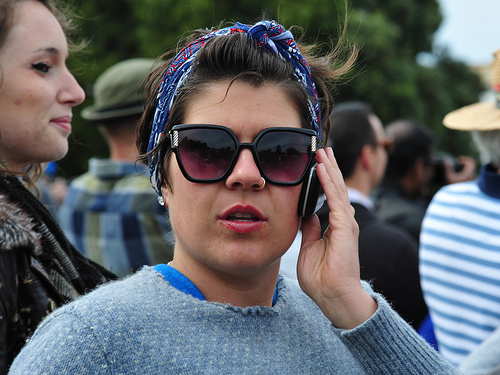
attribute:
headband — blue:
[144, 21, 319, 196]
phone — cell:
[290, 144, 330, 228]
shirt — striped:
[420, 165, 499, 367]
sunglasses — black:
[165, 116, 320, 197]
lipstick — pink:
[214, 199, 275, 243]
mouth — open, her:
[213, 200, 275, 234]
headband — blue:
[137, 17, 333, 181]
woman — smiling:
[3, 5, 103, 352]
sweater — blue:
[12, 255, 441, 374]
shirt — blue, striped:
[414, 162, 492, 367]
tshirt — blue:
[156, 252, 216, 301]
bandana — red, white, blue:
[139, 16, 324, 179]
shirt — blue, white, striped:
[426, 180, 483, 336]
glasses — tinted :
[158, 123, 318, 187]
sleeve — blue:
[338, 280, 463, 374]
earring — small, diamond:
[157, 195, 168, 209]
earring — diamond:
[154, 195, 167, 205]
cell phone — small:
[294, 158, 329, 219]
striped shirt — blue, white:
[416, 182, 498, 374]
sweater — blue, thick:
[8, 265, 460, 374]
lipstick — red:
[234, 220, 264, 226]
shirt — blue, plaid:
[58, 158, 175, 278]